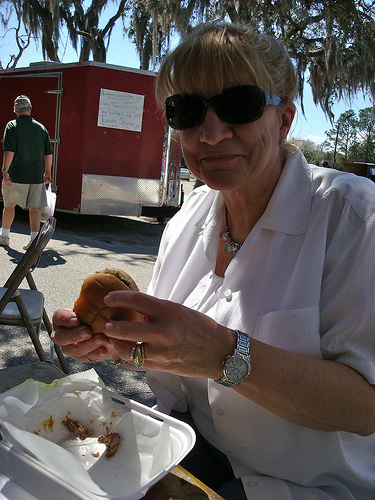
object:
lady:
[49, 22, 374, 499]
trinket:
[216, 228, 238, 254]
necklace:
[220, 212, 248, 257]